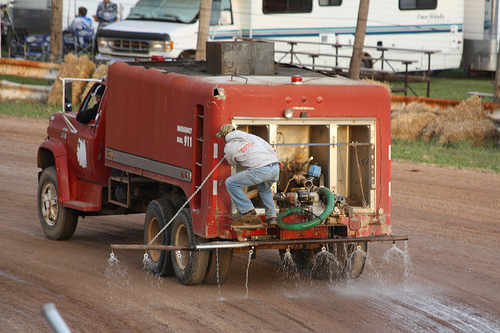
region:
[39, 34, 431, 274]
A red truck spraying water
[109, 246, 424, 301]
Water spraying on dirt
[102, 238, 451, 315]
Spraying water on a dirt track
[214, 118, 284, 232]
A man on the back of a truck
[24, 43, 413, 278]
A red truck on a dirt race track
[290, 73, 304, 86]
A red light on top of a truck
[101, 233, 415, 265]
A pipe spraying water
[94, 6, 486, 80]
An RV near the race track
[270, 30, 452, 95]
Bleacher seating near a race track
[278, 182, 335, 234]
A green hose on a red truck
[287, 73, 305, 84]
A siren in the picture.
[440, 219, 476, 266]
A dirt road in the picture.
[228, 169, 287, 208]
A pair of jeans in the photo.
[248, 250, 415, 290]
Water sprinkled on the road.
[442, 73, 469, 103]
Surface covered with grass.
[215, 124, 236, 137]
A brown cap in the picture.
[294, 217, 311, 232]
A green pipe in the picture.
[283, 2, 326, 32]
A white van in the picture.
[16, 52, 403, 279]
A red truck in the picture.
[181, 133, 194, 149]
Numbers 911 on side of truck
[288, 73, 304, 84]
Small red light on top of truck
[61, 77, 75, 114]
Side mirror attached to truck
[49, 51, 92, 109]
Bail of hay leaning against guardrail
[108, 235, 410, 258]
Long watering system hanging from truck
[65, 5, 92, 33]
Person sitting in the distance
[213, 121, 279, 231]
Man in grey hoodie riding on back of truck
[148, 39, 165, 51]
Clear headlight in front of camper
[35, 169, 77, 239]
Thick rubber tire on metal rim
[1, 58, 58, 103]
Rusted metal guardrail in background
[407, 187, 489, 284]
a brown ground covered with dirt.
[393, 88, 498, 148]
a bunch of hay.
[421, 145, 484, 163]
the grass is short and green.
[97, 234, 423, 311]
a watering pipe.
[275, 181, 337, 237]
a dark green hose.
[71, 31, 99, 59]
a blue chair.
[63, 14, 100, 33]
a man is wearing a blue and white shirt.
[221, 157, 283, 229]
a man is wearing blue jeans.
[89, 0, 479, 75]
a white and blue truck is parked in the drive way.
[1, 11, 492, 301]
a man is watering the road.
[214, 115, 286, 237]
a person is doing some thing in backside of the truck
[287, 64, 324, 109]
indicator of the truck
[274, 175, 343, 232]
a green colour hose of the truck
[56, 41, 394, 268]
a red colour truck moving on the road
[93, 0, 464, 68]
a white colour truck parked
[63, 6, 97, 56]
a person is sitting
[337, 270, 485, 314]
dirt road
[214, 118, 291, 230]
a person wearing cap, Jacket and blue jean